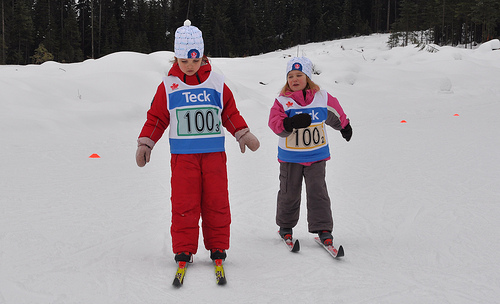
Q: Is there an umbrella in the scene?
A: No, there are no umbrellas.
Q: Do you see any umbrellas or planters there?
A: No, there are no umbrellas or planters.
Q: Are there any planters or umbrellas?
A: No, there are no umbrellas or planters.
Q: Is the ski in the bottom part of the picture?
A: Yes, the ski is in the bottom of the image.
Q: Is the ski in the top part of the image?
A: No, the ski is in the bottom of the image.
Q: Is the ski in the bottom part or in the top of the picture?
A: The ski is in the bottom of the image.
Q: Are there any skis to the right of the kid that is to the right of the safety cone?
A: Yes, there is a ski to the right of the kid.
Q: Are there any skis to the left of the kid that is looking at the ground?
A: No, the ski is to the right of the child.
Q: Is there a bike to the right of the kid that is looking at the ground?
A: No, there is a ski to the right of the child.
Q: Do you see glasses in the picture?
A: No, there are no glasses.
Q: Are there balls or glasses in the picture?
A: No, there are no glasses or balls.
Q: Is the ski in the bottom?
A: Yes, the ski is in the bottom of the image.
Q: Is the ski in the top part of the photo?
A: No, the ski is in the bottom of the image.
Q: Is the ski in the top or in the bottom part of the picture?
A: The ski is in the bottom of the image.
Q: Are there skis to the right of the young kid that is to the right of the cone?
A: Yes, there is a ski to the right of the child.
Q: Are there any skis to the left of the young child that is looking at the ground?
A: No, the ski is to the right of the kid.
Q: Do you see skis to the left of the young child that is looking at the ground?
A: No, the ski is to the right of the kid.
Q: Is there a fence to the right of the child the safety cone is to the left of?
A: No, there is a ski to the right of the kid.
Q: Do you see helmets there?
A: No, there are no helmets.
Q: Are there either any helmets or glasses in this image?
A: No, there are no helmets or glasses.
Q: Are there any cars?
A: No, there are no cars.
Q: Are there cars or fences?
A: No, there are no cars or fences.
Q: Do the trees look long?
A: Yes, the trees are long.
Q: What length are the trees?
A: The trees are long.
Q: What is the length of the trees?
A: The trees are long.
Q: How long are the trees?
A: The trees are long.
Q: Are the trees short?
A: No, the trees are long.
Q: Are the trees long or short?
A: The trees are long.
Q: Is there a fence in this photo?
A: No, there are no fences.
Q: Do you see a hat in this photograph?
A: Yes, there is a hat.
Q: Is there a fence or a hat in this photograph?
A: Yes, there is a hat.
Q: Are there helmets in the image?
A: No, there are no helmets.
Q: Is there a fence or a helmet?
A: No, there are no helmets or fences.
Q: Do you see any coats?
A: Yes, there is a coat.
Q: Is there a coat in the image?
A: Yes, there is a coat.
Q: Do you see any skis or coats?
A: Yes, there is a coat.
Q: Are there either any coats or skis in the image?
A: Yes, there is a coat.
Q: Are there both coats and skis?
A: Yes, there are both a coat and skis.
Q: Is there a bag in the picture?
A: No, there are no bags.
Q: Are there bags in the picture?
A: No, there are no bags.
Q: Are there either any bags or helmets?
A: No, there are no bags or helmets.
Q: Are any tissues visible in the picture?
A: No, there are no tissues.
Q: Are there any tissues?
A: No, there are no tissues.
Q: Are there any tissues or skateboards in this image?
A: No, there are no tissues or skateboards.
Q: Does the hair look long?
A: Yes, the hair is long.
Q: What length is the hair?
A: The hair is long.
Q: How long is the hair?
A: The hair is long.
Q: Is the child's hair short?
A: No, the hair is long.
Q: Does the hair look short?
A: No, the hair is long.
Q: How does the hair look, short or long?
A: The hair is long.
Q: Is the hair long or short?
A: The hair is long.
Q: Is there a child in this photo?
A: Yes, there is a child.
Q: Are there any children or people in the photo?
A: Yes, there is a child.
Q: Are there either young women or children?
A: Yes, there is a young child.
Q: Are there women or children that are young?
A: Yes, the child is young.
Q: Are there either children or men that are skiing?
A: Yes, the child is skiing.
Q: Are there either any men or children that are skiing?
A: Yes, the child is skiing.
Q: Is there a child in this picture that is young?
A: Yes, there is a young child.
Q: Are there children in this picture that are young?
A: Yes, there is a child that is young.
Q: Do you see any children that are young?
A: Yes, there is a child that is young.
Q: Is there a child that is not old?
A: Yes, there is an young child.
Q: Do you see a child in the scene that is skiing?
A: Yes, there is a child that is skiing.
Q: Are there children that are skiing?
A: Yes, there is a child that is skiing.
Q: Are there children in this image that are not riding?
A: Yes, there is a child that is skiing.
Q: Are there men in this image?
A: No, there are no men.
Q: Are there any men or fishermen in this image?
A: No, there are no men or fishermen.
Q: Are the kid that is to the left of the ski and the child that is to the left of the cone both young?
A: Yes, both the kid and the child are young.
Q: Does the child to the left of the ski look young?
A: Yes, the child is young.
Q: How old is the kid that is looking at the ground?
A: The child is young.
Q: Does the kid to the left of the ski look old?
A: No, the child is young.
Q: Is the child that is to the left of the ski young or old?
A: The kid is young.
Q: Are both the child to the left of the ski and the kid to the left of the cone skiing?
A: Yes, both the kid and the child are skiing.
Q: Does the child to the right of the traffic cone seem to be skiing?
A: Yes, the kid is skiing.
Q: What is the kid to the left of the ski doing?
A: The kid is skiing.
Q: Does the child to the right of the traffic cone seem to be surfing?
A: No, the kid is skiing.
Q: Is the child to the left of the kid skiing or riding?
A: The child is skiing.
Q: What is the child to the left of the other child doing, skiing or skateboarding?
A: The child is skiing.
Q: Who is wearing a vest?
A: The child is wearing a vest.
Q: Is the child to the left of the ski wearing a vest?
A: Yes, the child is wearing a vest.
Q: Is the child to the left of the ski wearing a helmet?
A: No, the kid is wearing a vest.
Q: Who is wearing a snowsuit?
A: The kid is wearing a snowsuit.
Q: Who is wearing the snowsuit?
A: The kid is wearing a snowsuit.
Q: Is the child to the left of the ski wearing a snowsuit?
A: Yes, the kid is wearing a snowsuit.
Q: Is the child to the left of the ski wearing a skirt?
A: No, the kid is wearing a snowsuit.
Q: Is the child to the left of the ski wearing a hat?
A: Yes, the kid is wearing a hat.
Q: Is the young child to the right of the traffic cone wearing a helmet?
A: No, the kid is wearing a hat.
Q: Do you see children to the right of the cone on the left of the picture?
A: Yes, there is a child to the right of the cone.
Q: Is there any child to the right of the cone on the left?
A: Yes, there is a child to the right of the cone.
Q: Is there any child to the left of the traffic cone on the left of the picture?
A: No, the child is to the right of the traffic cone.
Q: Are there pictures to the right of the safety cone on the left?
A: No, there is a child to the right of the traffic cone.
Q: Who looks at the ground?
A: The kid looks at the ground.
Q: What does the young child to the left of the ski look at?
A: The child looks at the ground.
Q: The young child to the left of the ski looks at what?
A: The child looks at the ground.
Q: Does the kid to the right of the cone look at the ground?
A: Yes, the child looks at the ground.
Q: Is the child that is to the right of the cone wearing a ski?
A: Yes, the child is wearing a ski.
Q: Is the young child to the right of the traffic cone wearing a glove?
A: No, the child is wearing a ski.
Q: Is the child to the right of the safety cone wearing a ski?
A: Yes, the child is wearing a ski.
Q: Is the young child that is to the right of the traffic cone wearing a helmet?
A: No, the child is wearing a ski.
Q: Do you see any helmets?
A: No, there are no helmets.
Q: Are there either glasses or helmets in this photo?
A: No, there are no helmets or glasses.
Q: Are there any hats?
A: Yes, there is a hat.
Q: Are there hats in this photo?
A: Yes, there is a hat.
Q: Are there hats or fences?
A: Yes, there is a hat.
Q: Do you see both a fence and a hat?
A: No, there is a hat but no fences.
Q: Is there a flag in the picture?
A: No, there are no flags.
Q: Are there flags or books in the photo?
A: No, there are no flags or books.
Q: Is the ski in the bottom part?
A: Yes, the ski is in the bottom of the image.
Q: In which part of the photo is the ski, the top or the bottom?
A: The ski is in the bottom of the image.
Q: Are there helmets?
A: No, there are no helmets.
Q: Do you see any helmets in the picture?
A: No, there are no helmets.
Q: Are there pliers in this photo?
A: No, there are no pliers.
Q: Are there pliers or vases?
A: No, there are no pliers or vases.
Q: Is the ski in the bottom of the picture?
A: Yes, the ski is in the bottom of the image.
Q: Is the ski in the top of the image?
A: No, the ski is in the bottom of the image.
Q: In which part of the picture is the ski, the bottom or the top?
A: The ski is in the bottom of the image.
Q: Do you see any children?
A: Yes, there is a child.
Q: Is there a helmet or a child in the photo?
A: Yes, there is a child.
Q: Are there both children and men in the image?
A: No, there is a child but no men.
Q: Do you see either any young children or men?
A: Yes, there is a young child.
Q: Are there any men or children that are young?
A: Yes, the child is young.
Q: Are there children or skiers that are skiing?
A: Yes, the child is skiing.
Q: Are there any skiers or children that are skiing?
A: Yes, the child is skiing.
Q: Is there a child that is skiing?
A: Yes, there is a child that is skiing.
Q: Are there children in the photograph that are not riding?
A: Yes, there is a child that is skiing.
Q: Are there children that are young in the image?
A: Yes, there is a young child.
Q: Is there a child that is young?
A: Yes, there is a child that is young.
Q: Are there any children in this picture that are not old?
A: Yes, there is an young child.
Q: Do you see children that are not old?
A: Yes, there is an young child.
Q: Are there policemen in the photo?
A: No, there are no policemen.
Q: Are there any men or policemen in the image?
A: No, there are no policemen or men.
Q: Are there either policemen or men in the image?
A: No, there are no policemen or men.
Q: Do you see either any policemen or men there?
A: No, there are no policemen or men.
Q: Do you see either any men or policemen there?
A: No, there are no policemen or men.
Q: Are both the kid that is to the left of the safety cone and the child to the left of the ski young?
A: Yes, both the child and the kid are young.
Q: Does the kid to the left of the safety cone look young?
A: Yes, the kid is young.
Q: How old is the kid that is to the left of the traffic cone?
A: The kid is young.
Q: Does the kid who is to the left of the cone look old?
A: No, the kid is young.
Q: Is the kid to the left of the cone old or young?
A: The kid is young.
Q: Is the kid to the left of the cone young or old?
A: The kid is young.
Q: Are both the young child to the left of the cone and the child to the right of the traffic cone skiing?
A: Yes, both the child and the kid are skiing.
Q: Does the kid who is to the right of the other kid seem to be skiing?
A: Yes, the kid is skiing.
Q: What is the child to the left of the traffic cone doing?
A: The kid is skiing.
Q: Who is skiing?
A: The kid is skiing.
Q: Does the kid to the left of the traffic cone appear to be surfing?
A: No, the kid is skiing.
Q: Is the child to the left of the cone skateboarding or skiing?
A: The child is skiing.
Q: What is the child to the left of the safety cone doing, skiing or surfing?
A: The kid is skiing.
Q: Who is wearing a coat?
A: The child is wearing a coat.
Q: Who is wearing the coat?
A: The child is wearing a coat.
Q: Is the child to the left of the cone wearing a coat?
A: Yes, the child is wearing a coat.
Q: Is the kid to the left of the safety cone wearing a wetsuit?
A: No, the child is wearing a coat.